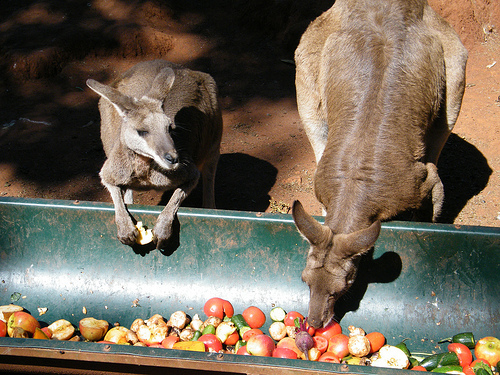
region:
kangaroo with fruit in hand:
[76, 47, 260, 289]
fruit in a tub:
[177, 280, 298, 350]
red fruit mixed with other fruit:
[175, 280, 282, 360]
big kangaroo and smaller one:
[96, 5, 458, 309]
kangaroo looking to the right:
[83, 69, 238, 259]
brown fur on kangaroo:
[335, 71, 440, 219]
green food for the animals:
[445, 320, 475, 355]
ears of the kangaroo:
[294, 201, 377, 254]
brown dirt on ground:
[229, 74, 292, 167]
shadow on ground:
[212, 13, 278, 138]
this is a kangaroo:
[273, 10, 460, 279]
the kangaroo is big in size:
[271, 1, 479, 289]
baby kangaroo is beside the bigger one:
[86, 46, 229, 231]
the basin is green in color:
[197, 230, 269, 279]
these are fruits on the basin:
[202, 305, 299, 355]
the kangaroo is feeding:
[290, 297, 341, 339]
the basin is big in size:
[204, 230, 269, 274]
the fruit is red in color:
[250, 307, 262, 317]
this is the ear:
[85, 78, 130, 113]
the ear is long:
[335, 215, 385, 254]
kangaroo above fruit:
[60, 50, 262, 236]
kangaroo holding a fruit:
[71, 54, 239, 255]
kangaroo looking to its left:
[68, 72, 238, 272]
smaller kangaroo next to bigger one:
[76, 32, 266, 222]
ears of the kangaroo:
[88, 75, 178, 117]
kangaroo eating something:
[281, 210, 386, 320]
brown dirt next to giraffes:
[227, 81, 292, 187]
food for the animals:
[123, 288, 281, 370]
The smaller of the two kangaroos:
[81, 55, 223, 259]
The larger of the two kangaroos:
[287, 1, 472, 333]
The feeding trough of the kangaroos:
[3, 192, 499, 373]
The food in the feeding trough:
[0, 293, 497, 373]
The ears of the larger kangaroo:
[287, 196, 382, 261]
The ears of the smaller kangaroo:
[80, 64, 178, 112]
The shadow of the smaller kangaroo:
[153, 149, 280, 216]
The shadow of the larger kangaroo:
[407, 121, 493, 229]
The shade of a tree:
[0, 0, 335, 206]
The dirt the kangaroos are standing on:
[1, 0, 499, 227]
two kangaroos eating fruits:
[94, 25, 456, 316]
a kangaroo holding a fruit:
[94, 63, 217, 259]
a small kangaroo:
[93, 52, 233, 198]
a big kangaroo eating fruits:
[291, 0, 481, 368]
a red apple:
[481, 327, 496, 365]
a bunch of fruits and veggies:
[40, 307, 468, 374]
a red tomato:
[245, 301, 267, 327]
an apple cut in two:
[51, 310, 73, 337]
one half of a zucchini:
[441, 324, 476, 346]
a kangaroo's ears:
[286, 195, 386, 257]